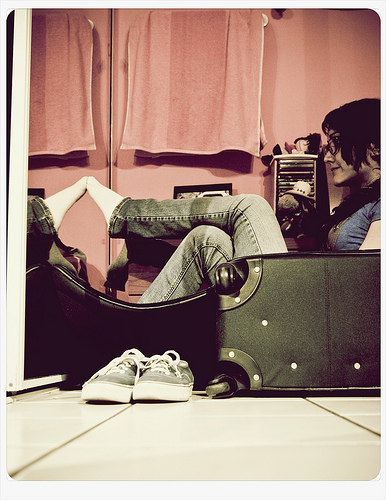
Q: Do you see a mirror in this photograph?
A: Yes, there is a mirror.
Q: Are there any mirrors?
A: Yes, there is a mirror.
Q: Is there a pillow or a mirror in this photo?
A: Yes, there is a mirror.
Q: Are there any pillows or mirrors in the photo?
A: Yes, there is a mirror.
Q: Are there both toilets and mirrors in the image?
A: No, there is a mirror but no toilets.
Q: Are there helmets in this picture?
A: No, there are no helmets.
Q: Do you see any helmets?
A: No, there are no helmets.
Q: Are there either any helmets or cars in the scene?
A: No, there are no helmets or cars.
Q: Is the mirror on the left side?
A: Yes, the mirror is on the left of the image.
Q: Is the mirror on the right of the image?
A: No, the mirror is on the left of the image.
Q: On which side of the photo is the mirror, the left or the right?
A: The mirror is on the left of the image.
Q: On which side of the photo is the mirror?
A: The mirror is on the left of the image.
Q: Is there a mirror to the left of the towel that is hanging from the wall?
A: Yes, there is a mirror to the left of the towel.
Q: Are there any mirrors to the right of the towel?
A: No, the mirror is to the left of the towel.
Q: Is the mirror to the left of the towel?
A: Yes, the mirror is to the left of the towel.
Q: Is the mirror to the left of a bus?
A: No, the mirror is to the left of the towel.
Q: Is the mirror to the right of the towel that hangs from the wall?
A: No, the mirror is to the left of the towel.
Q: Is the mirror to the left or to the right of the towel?
A: The mirror is to the left of the towel.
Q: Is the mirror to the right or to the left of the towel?
A: The mirror is to the left of the towel.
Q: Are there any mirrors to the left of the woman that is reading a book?
A: Yes, there is a mirror to the left of the woman.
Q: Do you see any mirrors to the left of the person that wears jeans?
A: Yes, there is a mirror to the left of the woman.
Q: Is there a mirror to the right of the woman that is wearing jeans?
A: No, the mirror is to the left of the woman.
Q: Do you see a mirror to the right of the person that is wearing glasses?
A: No, the mirror is to the left of the woman.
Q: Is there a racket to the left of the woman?
A: No, there is a mirror to the left of the woman.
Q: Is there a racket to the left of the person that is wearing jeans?
A: No, there is a mirror to the left of the woman.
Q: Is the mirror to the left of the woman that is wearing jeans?
A: Yes, the mirror is to the left of the woman.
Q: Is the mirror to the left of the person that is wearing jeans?
A: Yes, the mirror is to the left of the woman.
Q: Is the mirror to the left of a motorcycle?
A: No, the mirror is to the left of the woman.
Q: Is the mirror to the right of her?
A: No, the mirror is to the left of a woman.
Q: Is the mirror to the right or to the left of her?
A: The mirror is to the left of the woman.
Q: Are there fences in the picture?
A: No, there are no fences.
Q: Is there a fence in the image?
A: No, there are no fences.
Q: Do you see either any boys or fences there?
A: No, there are no fences or boys.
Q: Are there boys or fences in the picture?
A: No, there are no fences or boys.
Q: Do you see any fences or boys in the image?
A: No, there are no fences or boys.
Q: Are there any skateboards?
A: No, there are no skateboards.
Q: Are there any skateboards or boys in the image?
A: No, there are no skateboards or boys.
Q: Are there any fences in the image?
A: No, there are no fences.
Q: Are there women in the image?
A: Yes, there is a woman.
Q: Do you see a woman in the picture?
A: Yes, there is a woman.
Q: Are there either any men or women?
A: Yes, there is a woman.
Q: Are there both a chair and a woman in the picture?
A: No, there is a woman but no chairs.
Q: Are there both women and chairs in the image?
A: No, there is a woman but no chairs.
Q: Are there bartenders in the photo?
A: No, there are no bartenders.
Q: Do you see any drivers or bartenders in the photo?
A: No, there are no bartenders or drivers.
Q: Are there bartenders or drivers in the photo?
A: No, there are no bartenders or drivers.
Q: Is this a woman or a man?
A: This is a woman.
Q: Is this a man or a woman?
A: This is a woman.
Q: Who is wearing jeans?
A: The woman is wearing jeans.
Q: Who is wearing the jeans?
A: The woman is wearing jeans.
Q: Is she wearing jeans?
A: Yes, the woman is wearing jeans.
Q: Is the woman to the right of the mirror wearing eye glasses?
A: No, the woman is wearing jeans.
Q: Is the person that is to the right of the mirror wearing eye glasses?
A: No, the woman is wearing jeans.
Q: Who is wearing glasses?
A: The woman is wearing glasses.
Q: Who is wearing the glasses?
A: The woman is wearing glasses.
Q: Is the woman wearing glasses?
A: Yes, the woman is wearing glasses.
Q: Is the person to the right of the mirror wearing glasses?
A: Yes, the woman is wearing glasses.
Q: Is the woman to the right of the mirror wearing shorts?
A: No, the woman is wearing glasses.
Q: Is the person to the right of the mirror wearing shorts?
A: No, the woman is wearing glasses.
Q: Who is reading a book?
A: The woman is reading a book.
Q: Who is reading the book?
A: The woman is reading a book.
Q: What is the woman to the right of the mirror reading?
A: The woman is reading a book.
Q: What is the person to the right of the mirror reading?
A: The woman is reading a book.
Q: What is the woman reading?
A: The woman is reading a book.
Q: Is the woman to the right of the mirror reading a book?
A: Yes, the woman is reading a book.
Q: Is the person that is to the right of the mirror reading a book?
A: Yes, the woman is reading a book.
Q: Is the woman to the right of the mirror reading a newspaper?
A: No, the woman is reading a book.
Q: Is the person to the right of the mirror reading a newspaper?
A: No, the woman is reading a book.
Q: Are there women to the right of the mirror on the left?
A: Yes, there is a woman to the right of the mirror.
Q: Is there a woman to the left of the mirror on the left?
A: No, the woman is to the right of the mirror.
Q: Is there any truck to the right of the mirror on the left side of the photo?
A: No, there is a woman to the right of the mirror.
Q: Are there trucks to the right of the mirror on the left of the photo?
A: No, there is a woman to the right of the mirror.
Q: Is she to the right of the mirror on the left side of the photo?
A: Yes, the woman is to the right of the mirror.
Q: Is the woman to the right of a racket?
A: No, the woman is to the right of the mirror.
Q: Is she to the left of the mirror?
A: No, the woman is to the right of the mirror.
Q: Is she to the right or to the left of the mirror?
A: The woman is to the right of the mirror.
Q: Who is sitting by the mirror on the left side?
A: The woman is sitting by the mirror.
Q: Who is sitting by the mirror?
A: The woman is sitting by the mirror.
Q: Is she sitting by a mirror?
A: Yes, the woman is sitting by a mirror.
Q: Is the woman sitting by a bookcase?
A: No, the woman is sitting by a mirror.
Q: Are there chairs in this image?
A: No, there are no chairs.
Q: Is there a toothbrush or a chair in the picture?
A: No, there are no chairs or toothbrushes.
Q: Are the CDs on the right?
A: Yes, the CDs are on the right of the image.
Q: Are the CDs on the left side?
A: No, the CDs are on the right of the image.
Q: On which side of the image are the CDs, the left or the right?
A: The CDs are on the right of the image.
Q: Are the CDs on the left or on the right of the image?
A: The CDs are on the right of the image.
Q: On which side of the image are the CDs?
A: The CDs are on the right of the image.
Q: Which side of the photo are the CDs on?
A: The CDs are on the right of the image.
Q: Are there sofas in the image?
A: No, there are no sofas.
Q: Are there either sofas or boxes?
A: No, there are no sofas or boxes.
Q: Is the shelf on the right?
A: Yes, the shelf is on the right of the image.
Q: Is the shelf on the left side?
A: No, the shelf is on the right of the image.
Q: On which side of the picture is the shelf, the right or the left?
A: The shelf is on the right of the image.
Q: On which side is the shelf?
A: The shelf is on the right of the image.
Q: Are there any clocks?
A: No, there are no clocks.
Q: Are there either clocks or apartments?
A: No, there are no clocks or apartments.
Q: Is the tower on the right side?
A: Yes, the tower is on the right of the image.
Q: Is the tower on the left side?
A: No, the tower is on the right of the image.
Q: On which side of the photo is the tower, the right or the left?
A: The tower is on the right of the image.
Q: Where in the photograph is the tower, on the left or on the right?
A: The tower is on the right of the image.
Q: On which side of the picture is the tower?
A: The tower is on the right of the image.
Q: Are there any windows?
A: Yes, there is a window.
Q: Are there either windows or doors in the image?
A: Yes, there is a window.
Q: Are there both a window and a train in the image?
A: No, there is a window but no trains.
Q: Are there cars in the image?
A: No, there are no cars.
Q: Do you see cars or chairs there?
A: No, there are no cars or chairs.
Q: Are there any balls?
A: No, there are no balls.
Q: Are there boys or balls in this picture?
A: No, there are no balls or boys.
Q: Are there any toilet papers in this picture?
A: No, there are no toilet papers.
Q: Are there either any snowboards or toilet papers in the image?
A: No, there are no toilet papers or snowboards.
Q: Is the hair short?
A: Yes, the hair is short.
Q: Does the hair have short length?
A: Yes, the hair is short.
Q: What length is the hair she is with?
A: The hair is short.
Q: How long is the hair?
A: The hair is short.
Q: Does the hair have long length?
A: No, the hair is short.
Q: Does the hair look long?
A: No, the hair is short.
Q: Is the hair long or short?
A: The hair is short.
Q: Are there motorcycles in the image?
A: No, there are no motorcycles.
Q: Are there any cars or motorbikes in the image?
A: No, there are no motorbikes or cars.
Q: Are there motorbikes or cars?
A: No, there are no motorbikes or cars.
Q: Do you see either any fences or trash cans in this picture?
A: No, there are no fences or trash cans.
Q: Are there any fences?
A: No, there are no fences.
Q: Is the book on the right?
A: Yes, the book is on the right of the image.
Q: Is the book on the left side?
A: No, the book is on the right of the image.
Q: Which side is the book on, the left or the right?
A: The book is on the right of the image.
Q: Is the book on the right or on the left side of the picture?
A: The book is on the right of the image.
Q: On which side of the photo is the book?
A: The book is on the right of the image.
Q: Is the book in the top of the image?
A: Yes, the book is in the top of the image.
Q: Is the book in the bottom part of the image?
A: No, the book is in the top of the image.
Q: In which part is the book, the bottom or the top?
A: The book is in the top of the image.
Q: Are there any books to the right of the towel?
A: Yes, there is a book to the right of the towel.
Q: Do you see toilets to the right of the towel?
A: No, there is a book to the right of the towel.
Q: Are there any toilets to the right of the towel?
A: No, there is a book to the right of the towel.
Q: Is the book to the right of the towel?
A: Yes, the book is to the right of the towel.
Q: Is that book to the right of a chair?
A: No, the book is to the right of the towel.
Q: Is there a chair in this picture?
A: No, there are no chairs.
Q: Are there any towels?
A: Yes, there is a towel.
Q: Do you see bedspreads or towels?
A: Yes, there is a towel.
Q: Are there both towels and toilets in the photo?
A: No, there is a towel but no toilets.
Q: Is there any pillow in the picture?
A: No, there are no pillows.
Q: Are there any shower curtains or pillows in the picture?
A: No, there are no pillows or shower curtains.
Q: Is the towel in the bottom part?
A: No, the towel is in the top of the image.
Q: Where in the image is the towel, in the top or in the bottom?
A: The towel is in the top of the image.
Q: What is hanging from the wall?
A: The towel is hanging from the wall.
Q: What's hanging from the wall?
A: The towel is hanging from the wall.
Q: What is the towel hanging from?
A: The towel is hanging from the wall.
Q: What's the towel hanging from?
A: The towel is hanging from the wall.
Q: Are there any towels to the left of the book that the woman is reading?
A: Yes, there is a towel to the left of the book.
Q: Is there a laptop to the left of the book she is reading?
A: No, there is a towel to the left of the book.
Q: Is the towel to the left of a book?
A: Yes, the towel is to the left of a book.